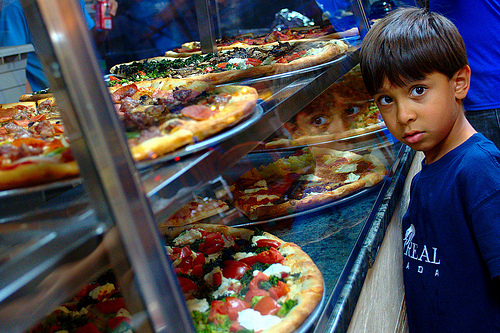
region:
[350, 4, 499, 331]
Young boy is in the foreground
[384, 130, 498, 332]
Young boy is wearing a blue shirt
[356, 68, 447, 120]
Young boy has brown eyes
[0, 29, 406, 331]
Pizzas are on display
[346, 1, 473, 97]
Young boy has short hair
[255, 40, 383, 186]
Young boy's face is in the reflection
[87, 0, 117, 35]
A soda can in the background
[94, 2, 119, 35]
Soda can is red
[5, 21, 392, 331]
Pizza's are fully cooked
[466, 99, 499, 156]
Person in the background is wearing jeans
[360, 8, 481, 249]
boy in blue shirt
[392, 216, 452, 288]
white logo on blue shirt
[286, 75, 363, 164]
boy's reflection on display case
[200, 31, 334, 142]
pizzas in display case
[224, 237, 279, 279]
tomatoes on top of pizza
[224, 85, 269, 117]
crust of cooked pizza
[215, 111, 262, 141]
metal tray under pizza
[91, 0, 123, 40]
can in person's hand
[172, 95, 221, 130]
pepperoni on pizza top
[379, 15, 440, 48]
light reflection on hair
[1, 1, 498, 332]
many pizzas, one kid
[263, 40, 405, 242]
kid reflected in pizza window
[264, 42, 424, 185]
reflection of kid is only partial, features his eyes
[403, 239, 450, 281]
real kid, not reflection wears shirt w/ the word 'real', all daps, on it. also 'a d a', all caps, maybe the end of canada [the word, not the country]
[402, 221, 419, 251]
a weird little picture above the word 'real' [helmet? jellyfish? puzzling @ this angle]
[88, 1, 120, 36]
someone, or someone's reflection, holds a coca cola can top left corner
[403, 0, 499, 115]
bright blue shirt, top right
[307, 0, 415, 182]
reflection of bright blue shirt mixed up w/ top of a cheese-sprinkling jar, top mid-right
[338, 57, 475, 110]
a large clean tan-brown ear, also bangs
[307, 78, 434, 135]
kid looks left, kid's reflection looks right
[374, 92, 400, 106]
The boy's left eye.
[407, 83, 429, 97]
The boy's right eye.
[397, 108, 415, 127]
The nose of the boy.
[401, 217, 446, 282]
The white design on the boy's shirt.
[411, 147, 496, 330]
The blue shirt the boy is wearing.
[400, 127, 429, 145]
The lips of the boy.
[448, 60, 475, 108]
The ear of the boy.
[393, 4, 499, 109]
The blue shirt the person behind the boy is wearing.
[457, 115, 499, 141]
The blue jeans the person behind the boy is wearing.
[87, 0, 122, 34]
The can of soda in the reflection of the glass.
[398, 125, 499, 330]
THE KID IS WEARING A BLUE SHIRT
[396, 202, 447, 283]
THE KIDS SHIRT HAS WRITING ON IT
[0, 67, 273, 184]
THIS IS A PIZZA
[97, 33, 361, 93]
THIS PIZZA HAS THIN CRUST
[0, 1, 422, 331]
THIS IS A DISPLAY CASE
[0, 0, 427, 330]
THE PIZZA IS BEHIND GLASS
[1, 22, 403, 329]
THE KID IS STANDING NEXT TO THE PIZZAS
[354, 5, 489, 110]
THE KID HAS BLACK HAIR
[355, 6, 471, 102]
THE KID HAS SHORT HAIR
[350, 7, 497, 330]
THE KID IS NOT SMILING